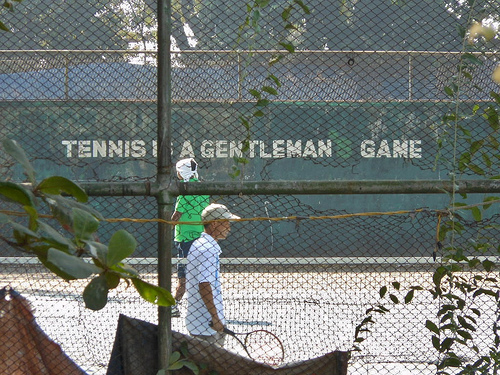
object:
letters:
[62, 139, 146, 157]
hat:
[199, 203, 239, 225]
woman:
[173, 150, 212, 319]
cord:
[5, 199, 497, 225]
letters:
[357, 139, 424, 159]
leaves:
[0, 136, 177, 306]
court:
[0, 254, 498, 372]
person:
[172, 153, 209, 322]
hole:
[244, 143, 498, 224]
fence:
[3, 3, 499, 374]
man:
[182, 197, 239, 347]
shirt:
[182, 231, 230, 335]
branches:
[343, 239, 499, 374]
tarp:
[104, 312, 349, 374]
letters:
[61, 138, 424, 159]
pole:
[153, 0, 174, 371]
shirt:
[172, 176, 211, 242]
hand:
[212, 318, 225, 335]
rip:
[241, 152, 499, 221]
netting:
[2, 4, 497, 371]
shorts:
[173, 237, 213, 279]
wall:
[39, 82, 497, 265]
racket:
[208, 321, 284, 368]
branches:
[28, 136, 337, 368]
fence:
[165, 69, 495, 341]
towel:
[168, 159, 201, 180]